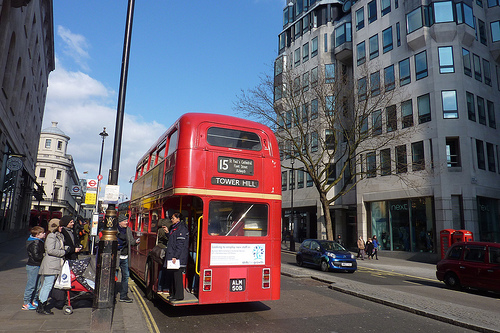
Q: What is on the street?
A: A bus.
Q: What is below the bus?
A: The street.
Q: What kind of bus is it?
A: Double decker.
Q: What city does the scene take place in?
A: London.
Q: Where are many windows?
A: On buildings.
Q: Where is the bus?
A: On the street.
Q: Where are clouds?
A: In the sky.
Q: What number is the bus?
A: 15.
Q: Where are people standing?
A: On the sidewalk.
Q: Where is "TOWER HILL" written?
A: On the bus.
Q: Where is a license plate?
A: On front of the bus.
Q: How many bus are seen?
A: 1.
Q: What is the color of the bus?
A: Red.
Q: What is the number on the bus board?
A: 15.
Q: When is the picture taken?
A: Daytime.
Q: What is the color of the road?
A: Grey.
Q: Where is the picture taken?
A: In the city.